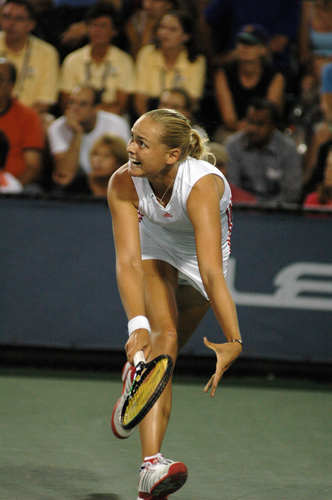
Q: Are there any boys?
A: No, there are no boys.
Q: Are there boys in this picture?
A: No, there are no boys.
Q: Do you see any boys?
A: No, there are no boys.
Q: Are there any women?
A: Yes, there is a woman.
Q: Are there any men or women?
A: Yes, there is a woman.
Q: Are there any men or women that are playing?
A: Yes, the woman is playing.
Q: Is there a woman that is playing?
A: Yes, there is a woman that is playing.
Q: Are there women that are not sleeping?
A: Yes, there is a woman that is playing.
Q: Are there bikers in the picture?
A: No, there are no bikers.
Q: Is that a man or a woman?
A: That is a woman.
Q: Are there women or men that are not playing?
A: No, there is a woman but she is playing.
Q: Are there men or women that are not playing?
A: No, there is a woman but she is playing.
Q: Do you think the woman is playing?
A: Yes, the woman is playing.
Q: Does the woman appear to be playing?
A: Yes, the woman is playing.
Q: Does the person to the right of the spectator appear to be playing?
A: Yes, the woman is playing.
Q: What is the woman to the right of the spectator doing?
A: The woman is playing.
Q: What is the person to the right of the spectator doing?
A: The woman is playing.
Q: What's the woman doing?
A: The woman is playing.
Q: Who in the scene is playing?
A: The woman is playing.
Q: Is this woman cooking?
A: No, the woman is playing.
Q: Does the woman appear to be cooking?
A: No, the woman is playing.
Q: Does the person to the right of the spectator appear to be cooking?
A: No, the woman is playing.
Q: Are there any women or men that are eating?
A: No, there is a woman but she is playing.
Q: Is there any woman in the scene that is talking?
A: No, there is a woman but she is playing.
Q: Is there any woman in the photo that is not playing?
A: No, there is a woman but she is playing.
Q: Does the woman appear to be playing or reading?
A: The woman is playing.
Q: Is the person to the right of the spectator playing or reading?
A: The woman is playing.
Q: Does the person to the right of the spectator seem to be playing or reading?
A: The woman is playing.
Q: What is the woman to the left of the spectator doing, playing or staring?
A: The woman is playing.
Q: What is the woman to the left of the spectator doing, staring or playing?
A: The woman is playing.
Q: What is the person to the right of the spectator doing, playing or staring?
A: The woman is playing.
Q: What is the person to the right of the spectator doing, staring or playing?
A: The woman is playing.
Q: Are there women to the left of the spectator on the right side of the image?
A: Yes, there is a woman to the left of the spectator.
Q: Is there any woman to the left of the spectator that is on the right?
A: Yes, there is a woman to the left of the spectator.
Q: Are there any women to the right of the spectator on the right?
A: No, the woman is to the left of the spectator.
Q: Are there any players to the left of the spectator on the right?
A: No, there is a woman to the left of the spectator.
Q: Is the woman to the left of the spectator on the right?
A: Yes, the woman is to the left of the spectator.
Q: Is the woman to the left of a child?
A: No, the woman is to the left of the spectator.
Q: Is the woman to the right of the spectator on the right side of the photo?
A: No, the woman is to the left of the spectator.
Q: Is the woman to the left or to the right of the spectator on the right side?
A: The woman is to the left of the spectator.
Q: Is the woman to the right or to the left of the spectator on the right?
A: The woman is to the left of the spectator.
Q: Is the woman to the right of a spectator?
A: Yes, the woman is to the right of a spectator.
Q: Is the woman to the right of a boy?
A: No, the woman is to the right of a spectator.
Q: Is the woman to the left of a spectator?
A: No, the woman is to the right of a spectator.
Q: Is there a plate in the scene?
A: No, there are no plates.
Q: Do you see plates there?
A: No, there are no plates.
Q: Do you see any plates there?
A: No, there are no plates.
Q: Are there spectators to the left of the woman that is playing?
A: Yes, there is a spectator to the left of the woman.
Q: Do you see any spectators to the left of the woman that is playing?
A: Yes, there is a spectator to the left of the woman.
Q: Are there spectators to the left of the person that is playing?
A: Yes, there is a spectator to the left of the woman.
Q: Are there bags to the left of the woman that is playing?
A: No, there is a spectator to the left of the woman.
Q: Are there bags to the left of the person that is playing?
A: No, there is a spectator to the left of the woman.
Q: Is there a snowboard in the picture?
A: No, there are no snowboards.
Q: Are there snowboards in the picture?
A: No, there are no snowboards.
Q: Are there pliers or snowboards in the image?
A: No, there are no snowboards or pliers.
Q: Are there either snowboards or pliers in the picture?
A: No, there are no snowboards or pliers.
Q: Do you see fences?
A: No, there are no fences.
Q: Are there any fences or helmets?
A: No, there are no fences or helmets.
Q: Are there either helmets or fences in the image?
A: No, there are no fences or helmets.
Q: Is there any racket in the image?
A: Yes, there is a racket.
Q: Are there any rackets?
A: Yes, there is a racket.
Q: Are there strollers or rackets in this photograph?
A: Yes, there is a racket.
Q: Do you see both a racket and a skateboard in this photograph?
A: No, there is a racket but no skateboards.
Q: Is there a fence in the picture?
A: No, there are no fences.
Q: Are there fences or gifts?
A: No, there are no fences or gifts.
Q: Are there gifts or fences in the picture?
A: No, there are no fences or gifts.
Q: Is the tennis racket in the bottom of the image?
A: Yes, the tennis racket is in the bottom of the image.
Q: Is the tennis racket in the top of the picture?
A: No, the tennis racket is in the bottom of the image.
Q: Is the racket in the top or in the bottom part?
A: The racket is in the bottom of the image.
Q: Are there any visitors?
A: No, there are no visitors.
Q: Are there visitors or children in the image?
A: No, there are no visitors or children.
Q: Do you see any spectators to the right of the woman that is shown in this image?
A: Yes, there is a spectator to the right of the woman.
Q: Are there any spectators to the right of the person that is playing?
A: Yes, there is a spectator to the right of the woman.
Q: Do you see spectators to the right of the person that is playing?
A: Yes, there is a spectator to the right of the woman.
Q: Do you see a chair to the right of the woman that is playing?
A: No, there is a spectator to the right of the woman.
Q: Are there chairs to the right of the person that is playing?
A: No, there is a spectator to the right of the woman.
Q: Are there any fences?
A: No, there are no fences.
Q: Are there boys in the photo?
A: No, there are no boys.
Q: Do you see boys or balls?
A: No, there are no boys or balls.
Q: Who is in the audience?
A: The spectators are in the audience.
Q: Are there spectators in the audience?
A: Yes, there are spectators in the audience.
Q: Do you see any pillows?
A: No, there are no pillows.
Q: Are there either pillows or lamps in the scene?
A: No, there are no pillows or lamps.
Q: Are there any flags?
A: No, there are no flags.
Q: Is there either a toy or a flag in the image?
A: No, there are no flags or toys.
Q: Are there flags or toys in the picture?
A: No, there are no flags or toys.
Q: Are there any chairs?
A: No, there are no chairs.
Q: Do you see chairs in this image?
A: No, there are no chairs.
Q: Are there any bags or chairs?
A: No, there are no chairs or bags.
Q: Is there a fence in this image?
A: No, there are no fences.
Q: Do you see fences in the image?
A: No, there are no fences.